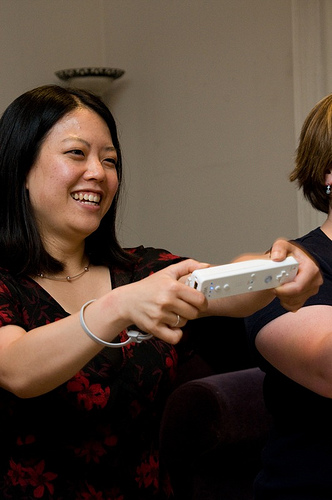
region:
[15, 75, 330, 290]
two people sitting down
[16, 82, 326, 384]
two people playing a game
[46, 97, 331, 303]
two people playing nintendo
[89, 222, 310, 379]
hands on a wii controller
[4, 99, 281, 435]
woman playing nintendo wii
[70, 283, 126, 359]
bracelet on woman's wrist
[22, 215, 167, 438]
shirt covered in red flowers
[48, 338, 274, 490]
purple couch behind women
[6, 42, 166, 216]
woman smiling while sitting down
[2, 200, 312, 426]
arms outstretched holding remote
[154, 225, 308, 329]
a white game controller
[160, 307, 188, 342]
a silver wedding ring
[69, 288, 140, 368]
a white band around her wrist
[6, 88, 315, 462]
woman holding a game controller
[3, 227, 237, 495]
a red and black shirt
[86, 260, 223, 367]
a womans hand on a controller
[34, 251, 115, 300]
a woman's necklace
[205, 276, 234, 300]
buttons on a white controller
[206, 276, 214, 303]
a blue light on the controller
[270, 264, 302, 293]
direction pad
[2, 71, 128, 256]
the woman is smiling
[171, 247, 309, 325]
the controller is white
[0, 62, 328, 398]
woman is holding a controller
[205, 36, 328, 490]
woman sitting next to her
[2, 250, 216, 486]
woman's shirt black and red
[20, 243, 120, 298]
woman's necklace is gold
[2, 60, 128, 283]
woman's hair is black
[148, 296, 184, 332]
woman wearing a ring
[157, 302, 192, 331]
the ring is gold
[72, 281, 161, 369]
controller wrapped around wrist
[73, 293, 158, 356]
white strap around a woman's wrist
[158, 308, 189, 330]
right ring finger with ring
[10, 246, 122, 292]
necklace with three beads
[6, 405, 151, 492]
red and black flower pattern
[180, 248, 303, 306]
white video game controller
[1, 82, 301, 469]
smiling woman playing a video game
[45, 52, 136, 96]
light fixture on a white wall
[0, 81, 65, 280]
shoulder length black hair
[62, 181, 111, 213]
a woman's smiling mouth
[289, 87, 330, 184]
short light brown hair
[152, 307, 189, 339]
a finger with a silver ring on it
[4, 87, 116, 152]
long black hair parted on the right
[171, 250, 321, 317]
two hands holding a WII remote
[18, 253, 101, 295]
a silver necklace with balls on it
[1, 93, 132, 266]
a happy woman of Asian descent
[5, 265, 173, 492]
a black dress with red flowers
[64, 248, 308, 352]
A Wii remote attched at the wrist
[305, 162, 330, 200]
an ear with a silver earring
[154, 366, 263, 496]
the back of a black chair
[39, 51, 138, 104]
the top of a round lamp